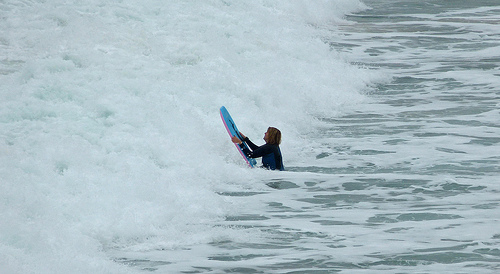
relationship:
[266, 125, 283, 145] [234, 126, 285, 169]
hair on a person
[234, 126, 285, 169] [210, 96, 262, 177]
person on board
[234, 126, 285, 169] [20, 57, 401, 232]
person out in ocean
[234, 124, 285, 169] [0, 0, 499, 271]
person close to beach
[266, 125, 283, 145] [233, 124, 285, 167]
hair on woman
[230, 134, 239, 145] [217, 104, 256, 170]
hand on board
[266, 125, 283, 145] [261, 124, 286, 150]
hair on head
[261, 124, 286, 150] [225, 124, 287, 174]
head on woman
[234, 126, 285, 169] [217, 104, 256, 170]
person on board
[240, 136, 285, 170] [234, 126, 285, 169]
wetsuit on person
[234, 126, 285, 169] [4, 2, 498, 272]
person in ocean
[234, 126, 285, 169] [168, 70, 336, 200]
person doing some surfing